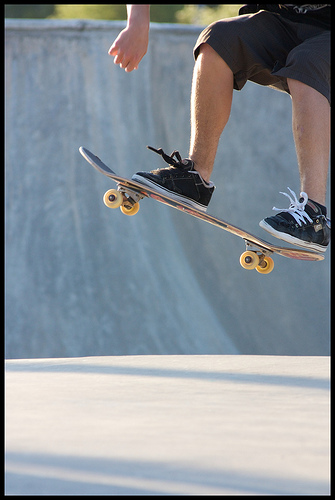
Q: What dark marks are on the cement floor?
A: Shadows.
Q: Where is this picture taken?
A: Skateboard rink.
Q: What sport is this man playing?
A: Skateboarding.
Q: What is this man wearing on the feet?
A: Black shoes.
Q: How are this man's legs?
A: Hairy.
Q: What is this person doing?
A: Performing a skateboard trick.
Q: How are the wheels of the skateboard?
A: Yellow.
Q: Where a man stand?
A: On a skateboard.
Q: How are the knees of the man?
A: Bend.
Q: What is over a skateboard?
A: A man.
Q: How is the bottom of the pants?
A: Short.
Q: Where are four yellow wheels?
A: Under the skateboard.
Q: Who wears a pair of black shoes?
A: A skater.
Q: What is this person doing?
A: Skateboarding.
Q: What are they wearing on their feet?
A: Sneakers.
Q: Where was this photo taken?
A: At the skate park.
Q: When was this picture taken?
A: Summertime.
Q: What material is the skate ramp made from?
A: Concrete.